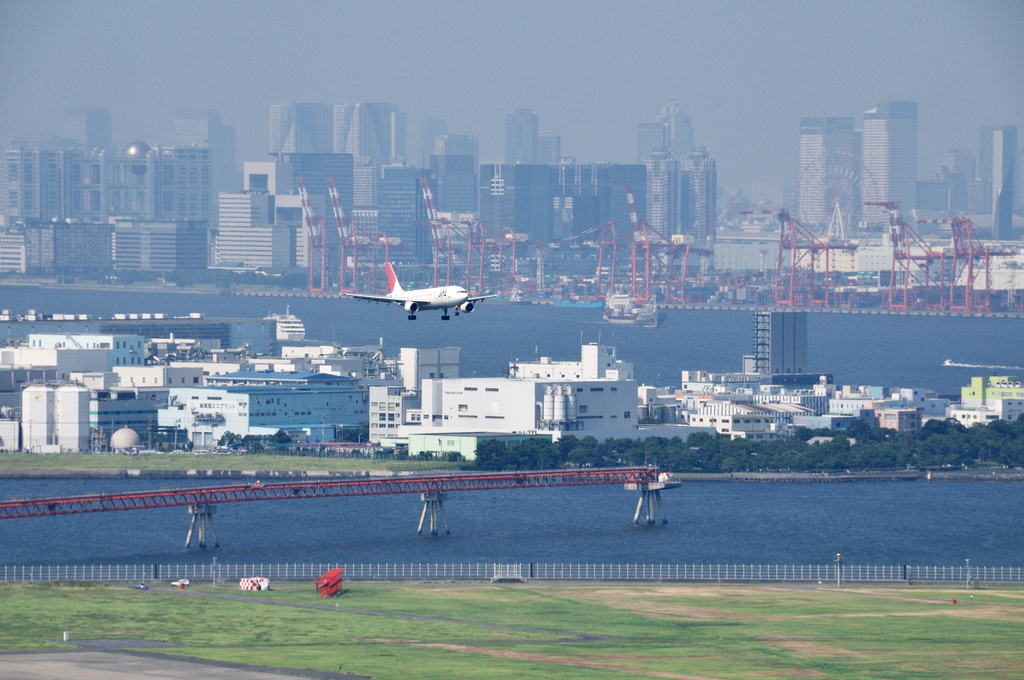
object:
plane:
[339, 262, 499, 321]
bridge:
[0, 458, 681, 548]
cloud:
[0, 0, 1024, 209]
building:
[367, 331, 715, 461]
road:
[0, 650, 351, 680]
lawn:
[0, 577, 1024, 678]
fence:
[0, 563, 1024, 583]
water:
[0, 478, 1024, 568]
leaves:
[461, 413, 1024, 471]